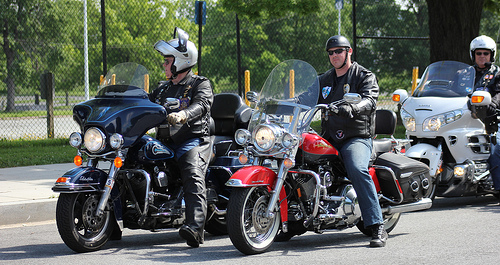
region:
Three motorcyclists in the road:
[43, 8, 497, 259]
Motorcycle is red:
[219, 114, 405, 256]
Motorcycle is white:
[371, 24, 498, 220]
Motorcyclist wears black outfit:
[146, 18, 218, 255]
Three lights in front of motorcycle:
[61, 126, 131, 158]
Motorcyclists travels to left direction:
[39, 11, 499, 251]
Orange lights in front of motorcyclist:
[386, 86, 487, 109]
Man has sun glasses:
[303, 28, 390, 112]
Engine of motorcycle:
[298, 173, 360, 231]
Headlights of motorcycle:
[392, 103, 462, 137]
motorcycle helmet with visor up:
[152, 25, 204, 76]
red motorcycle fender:
[226, 146, 296, 229]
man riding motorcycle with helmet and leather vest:
[308, 33, 382, 150]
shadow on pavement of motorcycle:
[126, 241, 307, 263]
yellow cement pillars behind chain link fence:
[241, 65, 300, 90]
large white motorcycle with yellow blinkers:
[388, 81, 498, 161]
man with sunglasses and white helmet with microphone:
[457, 31, 499, 73]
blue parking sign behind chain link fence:
[191, 2, 216, 39]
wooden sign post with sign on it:
[32, 60, 70, 155]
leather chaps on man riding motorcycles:
[171, 140, 227, 261]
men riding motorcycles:
[56, 22, 498, 253]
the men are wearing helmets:
[124, 7, 495, 134]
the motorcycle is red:
[227, 76, 399, 263]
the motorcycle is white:
[392, 29, 496, 209]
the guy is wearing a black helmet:
[300, 24, 387, 119]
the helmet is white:
[450, 26, 498, 91]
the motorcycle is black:
[44, 62, 297, 251]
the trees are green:
[11, 4, 386, 113]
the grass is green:
[1, 124, 131, 186]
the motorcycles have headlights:
[54, 107, 302, 192]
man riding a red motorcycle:
[237, 21, 443, 248]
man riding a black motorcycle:
[57, 19, 247, 239]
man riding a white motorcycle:
[397, 31, 494, 203]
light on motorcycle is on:
[230, 97, 309, 164]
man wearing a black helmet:
[282, 32, 393, 249]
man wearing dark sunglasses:
[284, 25, 396, 250]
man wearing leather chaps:
[138, 31, 213, 251]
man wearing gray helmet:
[143, 24, 215, 261]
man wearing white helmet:
[433, 18, 496, 206]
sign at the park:
[33, 58, 65, 146]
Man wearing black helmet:
[266, 35, 392, 247]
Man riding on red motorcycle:
[265, 27, 391, 247]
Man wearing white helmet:
[447, 35, 499, 204]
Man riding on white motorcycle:
[442, 32, 498, 202]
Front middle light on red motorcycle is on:
[250, 124, 278, 153]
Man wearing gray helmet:
[136, 30, 215, 251]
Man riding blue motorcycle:
[135, 28, 214, 258]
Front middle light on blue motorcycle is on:
[82, 127, 107, 156]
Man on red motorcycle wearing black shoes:
[272, 30, 391, 247]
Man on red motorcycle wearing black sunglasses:
[254, 35, 389, 247]